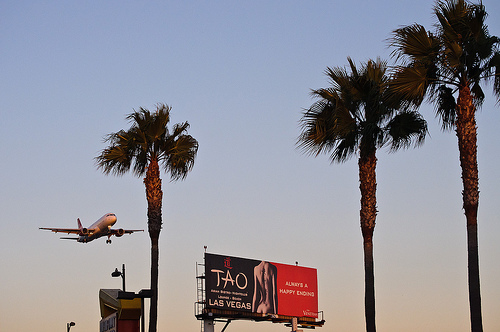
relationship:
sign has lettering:
[190, 252, 322, 309] [211, 263, 261, 315]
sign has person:
[191, 252, 326, 329] [253, 258, 280, 322]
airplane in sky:
[37, 209, 146, 248] [0, 0, 499, 330]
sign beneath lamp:
[100, 315, 115, 327] [110, 262, 127, 285]